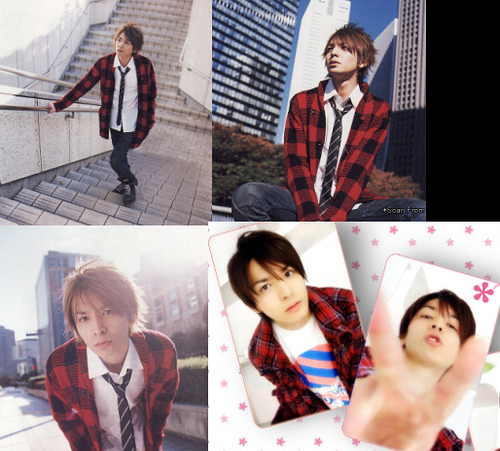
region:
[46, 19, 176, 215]
Girl climbing the stairs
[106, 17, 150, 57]
Girl has dark hair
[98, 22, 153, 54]
Girl's hair is brown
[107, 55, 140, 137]
Girl is wearing white shirt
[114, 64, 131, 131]
Girl is wearing a tie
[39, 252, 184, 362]
The girl has messy hair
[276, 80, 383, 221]
Girl is wearing a warm shirt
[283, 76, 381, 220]
Girl's shirt is plaid squares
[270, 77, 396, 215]
The girls shirt is red and black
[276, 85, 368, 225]
Girl's shirt has long sleeves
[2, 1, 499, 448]
young asian guy, in asia, putting together modeling shots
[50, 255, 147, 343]
nice haircut, good-not too heavy-bleach job, lower left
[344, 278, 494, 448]
a western peace sign, done w/ fingers, & an international asterisk in one corner of one card [& also in pink]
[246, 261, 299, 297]
nicely shaped eyebrows, pic second to right on bottom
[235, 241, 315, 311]
same w/ the way the hair's done, same pic, to frame the eyes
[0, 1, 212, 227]
full length, fully dressed modeling shot, in the middle of many steps, up & down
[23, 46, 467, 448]
the e'erpresent red+black lumberjacket i dont get, but i dont have to get everything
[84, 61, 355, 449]
long skinny old new wave tie, dark w/ silvertone or white stripes, three shots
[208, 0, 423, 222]
same dude, seated, in dark pants, amid skyscrapers, w/ reddish hair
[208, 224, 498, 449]
little pink stars on white behind two card headshots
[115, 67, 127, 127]
the long dark tie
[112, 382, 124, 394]
the knot in the tie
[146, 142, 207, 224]
the gray stairs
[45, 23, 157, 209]
the boy walking up the stairs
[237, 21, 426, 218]
the boy sitting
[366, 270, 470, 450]
the boy making a peace sign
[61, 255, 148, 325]
the long hair on the boy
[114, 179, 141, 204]
the dark shoes on the boy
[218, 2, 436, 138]
the buildings behind the boy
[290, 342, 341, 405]
the design on the white shirt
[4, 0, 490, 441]
four different pictures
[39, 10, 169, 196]
guy standing on the steps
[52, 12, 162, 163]
man wearing a red and black jacket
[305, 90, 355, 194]
a black and white tie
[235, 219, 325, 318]
the man has dark brown hair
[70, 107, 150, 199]
the man is wearing jeans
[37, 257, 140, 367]
the man is looking in the camera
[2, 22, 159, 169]
the man is holding the rail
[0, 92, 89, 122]
the rail is silver metal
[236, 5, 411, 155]
buildings are in the background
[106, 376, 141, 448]
black and white striped necktie